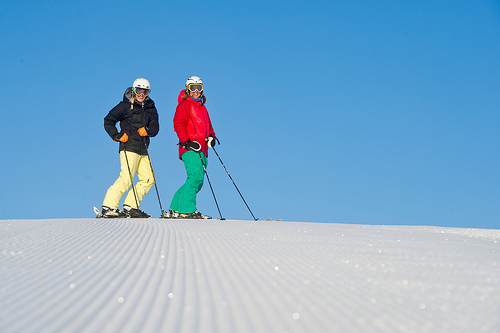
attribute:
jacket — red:
[173, 92, 215, 153]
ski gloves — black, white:
[178, 138, 203, 151]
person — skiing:
[167, 72, 221, 209]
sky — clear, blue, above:
[0, 1, 499, 231]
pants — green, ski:
[170, 148, 210, 215]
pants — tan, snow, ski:
[103, 146, 153, 210]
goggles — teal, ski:
[123, 79, 158, 101]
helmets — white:
[109, 52, 218, 101]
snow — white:
[1, 217, 499, 331]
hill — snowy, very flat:
[0, 220, 498, 332]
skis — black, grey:
[82, 202, 190, 229]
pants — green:
[169, 145, 207, 219]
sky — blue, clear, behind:
[6, 7, 497, 132]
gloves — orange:
[115, 122, 150, 144]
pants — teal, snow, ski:
[174, 154, 206, 209]